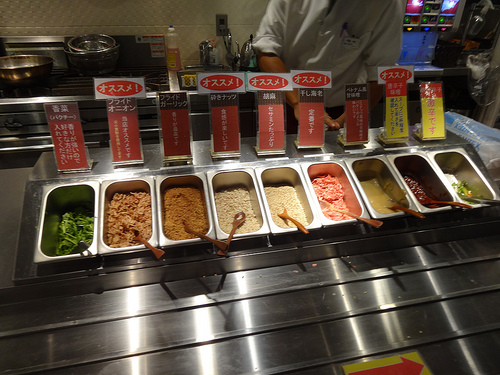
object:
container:
[7, 130, 499, 289]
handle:
[131, 236, 168, 258]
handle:
[184, 220, 226, 248]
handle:
[214, 210, 246, 258]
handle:
[278, 207, 309, 235]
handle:
[335, 206, 383, 228]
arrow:
[343, 355, 425, 375]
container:
[296, 157, 373, 230]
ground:
[425, 129, 466, 147]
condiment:
[53, 202, 96, 257]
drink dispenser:
[384, 0, 462, 78]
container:
[31, 178, 102, 267]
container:
[98, 175, 158, 257]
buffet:
[29, 178, 99, 264]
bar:
[0, 284, 57, 331]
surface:
[199, 303, 406, 350]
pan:
[0, 51, 56, 91]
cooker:
[40, 74, 92, 97]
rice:
[276, 182, 296, 223]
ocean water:
[100, 182, 154, 250]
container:
[208, 160, 269, 253]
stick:
[276, 206, 313, 238]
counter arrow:
[323, 337, 444, 373]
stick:
[122, 227, 168, 261]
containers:
[102, 169, 217, 254]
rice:
[160, 185, 209, 242]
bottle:
[164, 24, 181, 70]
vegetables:
[49, 207, 96, 257]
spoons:
[122, 223, 171, 261]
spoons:
[422, 196, 473, 210]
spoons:
[328, 203, 385, 230]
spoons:
[274, 212, 310, 238]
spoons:
[216, 209, 247, 259]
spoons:
[131, 232, 166, 261]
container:
[394, 150, 452, 225]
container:
[344, 148, 414, 223]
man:
[250, 0, 406, 133]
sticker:
[339, 351, 433, 373]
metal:
[61, 32, 118, 65]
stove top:
[0, 33, 181, 107]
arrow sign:
[339, 351, 433, 375]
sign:
[41, 101, 96, 176]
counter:
[2, 228, 498, 373]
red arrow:
[346, 355, 426, 374]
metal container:
[376, 144, 468, 216]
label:
[87, 67, 157, 104]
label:
[187, 61, 246, 94]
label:
[240, 65, 297, 101]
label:
[282, 67, 335, 91]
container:
[382, 150, 465, 216]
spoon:
[70, 235, 92, 256]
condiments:
[50, 201, 95, 258]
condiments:
[100, 184, 154, 249]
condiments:
[211, 177, 265, 239]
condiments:
[307, 169, 355, 223]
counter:
[339, 348, 433, 373]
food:
[212, 183, 261, 234]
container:
[203, 164, 272, 242]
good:
[48, 163, 471, 258]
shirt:
[249, 0, 406, 111]